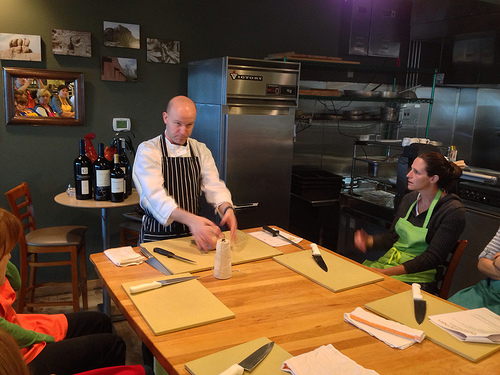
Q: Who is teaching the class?
A: A man.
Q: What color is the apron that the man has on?
A: Black and white.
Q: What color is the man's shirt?
A: White.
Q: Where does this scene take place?
A: In a kitchen.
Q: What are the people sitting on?
A: Stools.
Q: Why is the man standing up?
A: He is teaching the people that are sitting down.